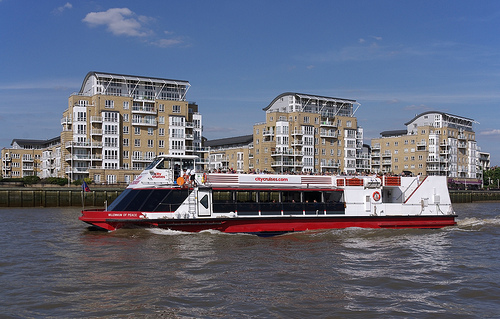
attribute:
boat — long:
[91, 159, 454, 240]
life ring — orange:
[369, 188, 384, 203]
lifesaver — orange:
[369, 189, 387, 203]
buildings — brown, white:
[69, 74, 202, 161]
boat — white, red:
[83, 150, 465, 240]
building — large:
[60, 72, 209, 161]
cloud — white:
[102, 13, 145, 35]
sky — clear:
[219, 31, 285, 87]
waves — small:
[357, 266, 417, 284]